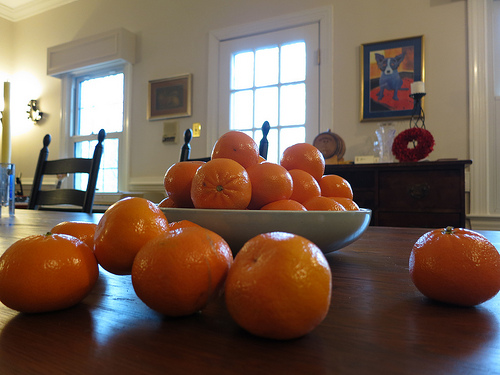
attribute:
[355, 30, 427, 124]
picture — framed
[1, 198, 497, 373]
table — brown, wooden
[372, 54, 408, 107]
pciture — framed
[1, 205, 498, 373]
dining table — large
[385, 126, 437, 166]
flower — red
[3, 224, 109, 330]
orange — small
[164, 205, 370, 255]
bowl — white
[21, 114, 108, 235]
chair — wooden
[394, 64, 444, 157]
stick — candle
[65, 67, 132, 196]
window — lightened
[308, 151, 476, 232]
cabinet — brown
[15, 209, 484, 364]
table — brown